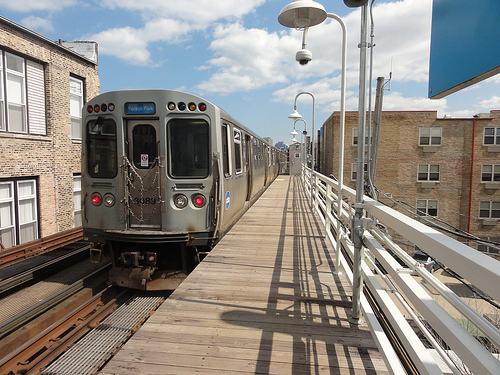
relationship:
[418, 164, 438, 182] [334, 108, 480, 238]
window on building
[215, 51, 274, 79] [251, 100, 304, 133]
clouds in sky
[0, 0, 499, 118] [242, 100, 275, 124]
clouds in sky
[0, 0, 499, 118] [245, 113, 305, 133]
clouds in sky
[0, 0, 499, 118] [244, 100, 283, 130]
clouds in sky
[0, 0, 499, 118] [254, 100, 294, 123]
clouds in sky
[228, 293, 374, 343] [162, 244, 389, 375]
shadow of lights on ground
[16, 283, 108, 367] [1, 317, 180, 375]
train tracks on ground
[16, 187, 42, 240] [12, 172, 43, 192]
window on building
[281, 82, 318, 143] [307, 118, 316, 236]
street light on pole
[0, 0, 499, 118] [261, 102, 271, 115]
clouds in sky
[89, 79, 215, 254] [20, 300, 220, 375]
train on tracks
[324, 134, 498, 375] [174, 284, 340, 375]
railing on platform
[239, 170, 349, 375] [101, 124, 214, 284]
platform by train